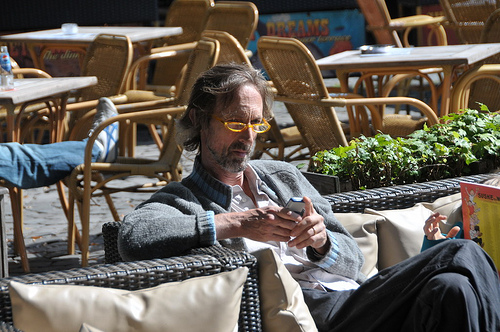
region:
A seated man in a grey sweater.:
[108, 67, 495, 330]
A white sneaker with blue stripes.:
[91, 87, 120, 163]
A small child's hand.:
[420, 211, 459, 245]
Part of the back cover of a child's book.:
[459, 179, 499, 255]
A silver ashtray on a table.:
[361, 40, 401, 55]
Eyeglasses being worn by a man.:
[214, 108, 275, 139]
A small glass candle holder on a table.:
[58, 16, 82, 38]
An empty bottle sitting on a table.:
[0, 39, 24, 99]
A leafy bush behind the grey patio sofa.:
[305, 107, 498, 187]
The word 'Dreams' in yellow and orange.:
[265, 15, 336, 39]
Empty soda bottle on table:
[1, 40, 19, 95]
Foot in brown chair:
[71, 95, 128, 170]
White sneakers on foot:
[84, 83, 125, 168]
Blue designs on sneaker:
[104, 130, 113, 146]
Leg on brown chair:
[2, 135, 94, 185]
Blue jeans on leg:
[6, 140, 70, 182]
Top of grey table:
[31, 75, 72, 92]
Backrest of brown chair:
[91, 35, 129, 83]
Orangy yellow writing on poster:
[267, 16, 331, 38]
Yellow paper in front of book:
[481, 201, 498, 242]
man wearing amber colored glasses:
[172, 59, 273, 186]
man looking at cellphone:
[118, 62, 364, 277]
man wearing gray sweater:
[108, 66, 485, 328]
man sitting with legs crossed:
[117, 53, 498, 328]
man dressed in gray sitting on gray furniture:
[117, 58, 470, 330]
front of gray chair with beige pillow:
[5, 249, 267, 329]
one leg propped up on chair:
[1, 97, 133, 182]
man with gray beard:
[173, 62, 268, 183]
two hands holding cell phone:
[240, 194, 331, 255]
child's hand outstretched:
[421, 211, 460, 243]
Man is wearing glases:
[211, 111, 280, 144]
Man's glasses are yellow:
[221, 117, 231, 131]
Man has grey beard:
[217, 153, 244, 177]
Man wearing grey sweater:
[150, 188, 183, 228]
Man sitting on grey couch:
[111, 271, 166, 279]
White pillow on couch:
[168, 295, 227, 324]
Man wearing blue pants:
[391, 271, 467, 306]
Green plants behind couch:
[357, 138, 422, 166]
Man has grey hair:
[200, 68, 243, 89]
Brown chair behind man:
[148, 96, 178, 168]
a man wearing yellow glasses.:
[175, 66, 302, 180]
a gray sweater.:
[104, 159, 363, 328]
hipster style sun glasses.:
[209, 111, 290, 137]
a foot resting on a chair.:
[0, 105, 144, 190]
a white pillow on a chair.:
[6, 247, 254, 329]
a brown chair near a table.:
[251, 36, 446, 156]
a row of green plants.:
[301, 86, 498, 208]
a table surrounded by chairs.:
[306, 42, 498, 73]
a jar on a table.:
[61, 23, 80, 43]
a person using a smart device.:
[254, 196, 335, 237]